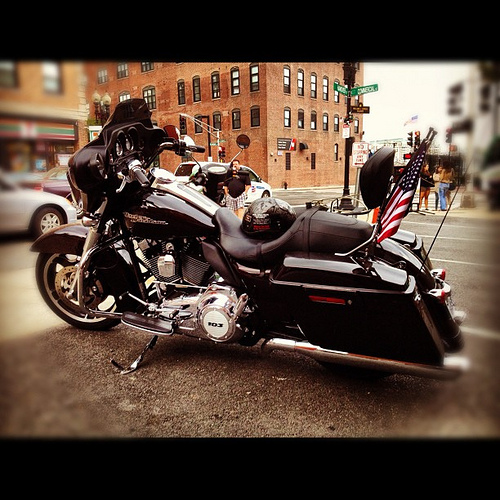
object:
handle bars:
[128, 158, 149, 191]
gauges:
[113, 138, 124, 157]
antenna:
[416, 154, 478, 273]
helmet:
[239, 195, 298, 239]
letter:
[252, 226, 255, 231]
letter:
[256, 225, 260, 230]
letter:
[257, 226, 260, 231]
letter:
[261, 225, 264, 231]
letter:
[265, 225, 269, 230]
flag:
[376, 138, 428, 243]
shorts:
[224, 191, 247, 213]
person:
[416, 162, 433, 212]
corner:
[412, 201, 464, 221]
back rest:
[359, 144, 396, 212]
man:
[220, 158, 251, 220]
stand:
[108, 334, 158, 376]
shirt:
[222, 166, 253, 199]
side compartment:
[261, 255, 445, 368]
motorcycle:
[29, 97, 469, 377]